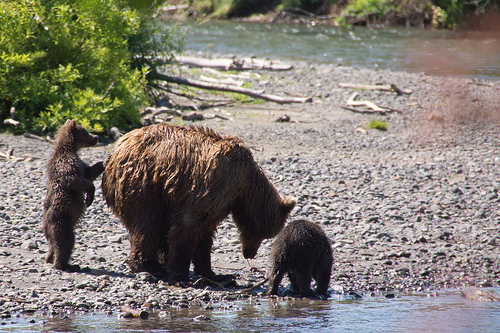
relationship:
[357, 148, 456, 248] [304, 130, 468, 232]
rocks in dirt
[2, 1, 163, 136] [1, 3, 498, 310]
bush on ground